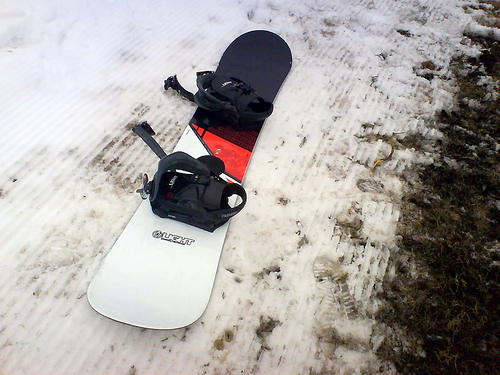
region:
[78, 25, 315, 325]
a snowboard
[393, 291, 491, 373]
the grasso on the ground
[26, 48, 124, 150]
the snow on the ground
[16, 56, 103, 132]
snow is white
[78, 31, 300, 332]
snowboard is on the ground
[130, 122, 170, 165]
straps on the board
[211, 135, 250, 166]
the snowboard is red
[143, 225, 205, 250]
brand of the snowboard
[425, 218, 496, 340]
the weeds are green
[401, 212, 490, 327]
weeds on the ground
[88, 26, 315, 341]
That is a snowboard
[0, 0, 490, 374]
That is snow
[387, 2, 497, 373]
That is earth with less snow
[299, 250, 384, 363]
that is a foot print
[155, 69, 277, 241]
Those are foot straps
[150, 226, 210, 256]
That is the name of the snowboard manufacturer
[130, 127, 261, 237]
That is the foot strap for the left foot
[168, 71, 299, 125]
That is the foot strap for the right foot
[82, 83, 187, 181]
That is a tire track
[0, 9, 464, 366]
The snow is freshly raked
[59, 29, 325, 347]
snowboard on the ground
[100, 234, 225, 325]
white part of the board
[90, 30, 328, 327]
colorful snowboard on ground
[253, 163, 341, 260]
snow under the board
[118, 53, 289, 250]
places to put feet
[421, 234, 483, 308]
grass next to snow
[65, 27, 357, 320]
snowboard not being used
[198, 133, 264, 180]
orange part of the snowboard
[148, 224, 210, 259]
writing on the snowboard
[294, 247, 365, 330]
footprint in the snow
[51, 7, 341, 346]
Board is red and white and black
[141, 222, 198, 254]
"Light" on the board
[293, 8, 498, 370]
Grass sticking out of snow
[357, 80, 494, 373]
Grass is dark green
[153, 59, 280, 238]
A place for feet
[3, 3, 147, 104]
A lot of snow in the corner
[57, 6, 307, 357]
No one is on the board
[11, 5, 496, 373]
It is sunny outside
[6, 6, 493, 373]
It is day time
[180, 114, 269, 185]
The middle is red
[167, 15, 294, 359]
Snow board on the ground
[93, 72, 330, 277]
Snow board on the ground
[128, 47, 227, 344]
Snow board on the ground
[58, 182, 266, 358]
Snow board on the ground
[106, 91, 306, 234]
Black red and white snow board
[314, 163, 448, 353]
Snow on the ground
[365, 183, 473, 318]
snow and mud on the ground